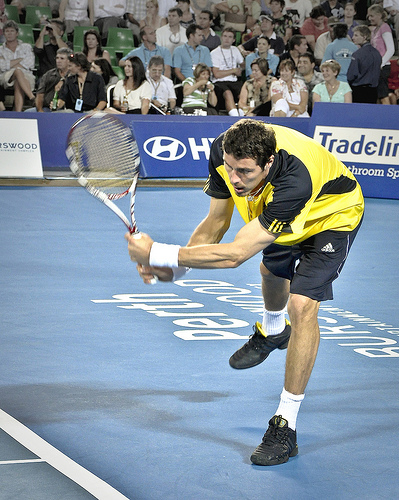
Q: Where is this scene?
A: A tennis court.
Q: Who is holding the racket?
A: The tennis player.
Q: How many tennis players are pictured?
A: One.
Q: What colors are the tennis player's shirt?
A: Black and yellow.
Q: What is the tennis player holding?
A: A racket.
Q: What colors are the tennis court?
A: Blue and white.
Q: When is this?
A: Daytime.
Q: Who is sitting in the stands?
A: Spectators.